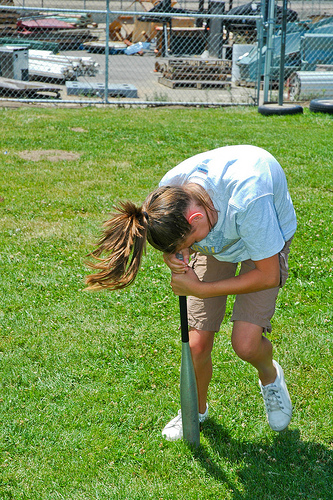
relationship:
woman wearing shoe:
[126, 145, 312, 461] [256, 369, 296, 431]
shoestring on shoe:
[266, 388, 286, 411] [256, 369, 296, 431]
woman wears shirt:
[126, 145, 312, 461] [157, 151, 296, 244]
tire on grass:
[307, 79, 332, 116] [134, 129, 189, 146]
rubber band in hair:
[131, 201, 176, 235] [110, 202, 156, 286]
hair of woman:
[110, 202, 156, 286] [126, 145, 312, 461]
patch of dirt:
[17, 143, 35, 164] [24, 149, 87, 165]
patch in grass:
[17, 143, 35, 164] [134, 129, 189, 146]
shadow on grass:
[230, 435, 329, 495] [134, 129, 189, 146]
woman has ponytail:
[126, 145, 312, 461] [106, 221, 127, 298]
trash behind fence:
[226, 4, 327, 98] [197, 26, 224, 40]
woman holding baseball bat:
[126, 145, 312, 461] [158, 295, 218, 444]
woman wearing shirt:
[126, 145, 312, 461] [157, 151, 296, 244]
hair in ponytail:
[110, 202, 156, 286] [106, 221, 127, 298]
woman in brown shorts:
[126, 145, 312, 461] [201, 302, 292, 327]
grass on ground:
[134, 129, 189, 146] [230, 117, 239, 121]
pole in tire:
[276, 30, 314, 91] [261, 89, 303, 125]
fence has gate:
[197, 26, 224, 40] [256, 3, 274, 105]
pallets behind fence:
[168, 53, 236, 89] [197, 26, 224, 40]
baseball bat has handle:
[158, 295, 218, 444] [168, 301, 195, 348]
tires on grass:
[264, 86, 332, 119] [134, 129, 189, 146]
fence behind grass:
[197, 26, 224, 40] [134, 129, 189, 146]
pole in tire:
[276, 30, 314, 91] [307, 79, 332, 116]